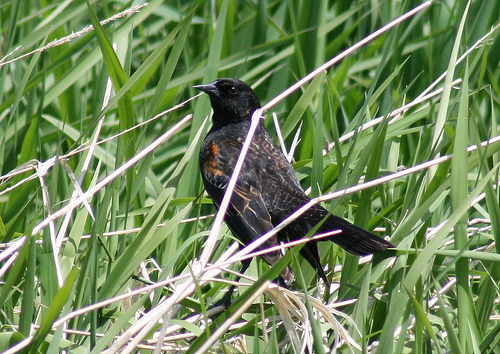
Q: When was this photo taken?
A: During the daytime.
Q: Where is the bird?
A: Sitting on the grass.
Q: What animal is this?
A: A bird.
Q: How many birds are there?
A: One.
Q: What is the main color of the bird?
A: Black.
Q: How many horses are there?
A: Zero.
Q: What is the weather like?
A: Bright and sunny.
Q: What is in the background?
A: Green grasses.